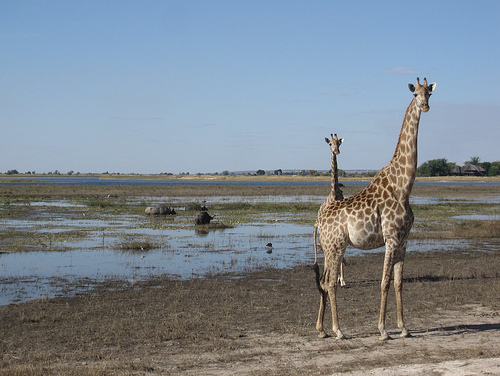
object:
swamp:
[3, 176, 498, 373]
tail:
[307, 219, 322, 272]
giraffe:
[312, 80, 444, 340]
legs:
[375, 231, 411, 346]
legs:
[303, 245, 357, 351]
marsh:
[4, 181, 499, 314]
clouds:
[51, 10, 389, 128]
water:
[2, 198, 453, 315]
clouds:
[290, 70, 499, 167]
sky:
[0, 0, 499, 172]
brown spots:
[378, 176, 404, 216]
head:
[323, 133, 344, 168]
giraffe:
[326, 163, 345, 210]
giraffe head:
[400, 75, 437, 119]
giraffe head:
[321, 126, 348, 159]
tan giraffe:
[322, 74, 438, 350]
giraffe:
[311, 72, 437, 346]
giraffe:
[312, 72, 445, 343]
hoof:
[332, 318, 349, 340]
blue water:
[1, 174, 498, 186]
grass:
[184, 273, 271, 299]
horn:
[413, 75, 420, 85]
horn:
[422, 73, 429, 85]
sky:
[45, 28, 307, 112]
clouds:
[373, 55, 429, 78]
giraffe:
[311, 132, 347, 288]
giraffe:
[305, 77, 439, 354]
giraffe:
[316, 132, 358, 192]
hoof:
[399, 325, 412, 340]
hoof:
[376, 329, 391, 344]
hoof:
[333, 331, 349, 341]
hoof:
[314, 332, 330, 341]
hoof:
[337, 279, 351, 287]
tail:
[299, 245, 333, 298]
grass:
[110, 283, 237, 353]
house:
[432, 158, 488, 175]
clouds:
[3, 117, 126, 170]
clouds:
[253, 80, 381, 157]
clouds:
[432, 89, 499, 157]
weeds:
[22, 227, 94, 249]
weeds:
[82, 202, 145, 220]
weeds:
[1, 201, 61, 223]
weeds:
[227, 206, 277, 226]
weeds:
[111, 225, 167, 252]